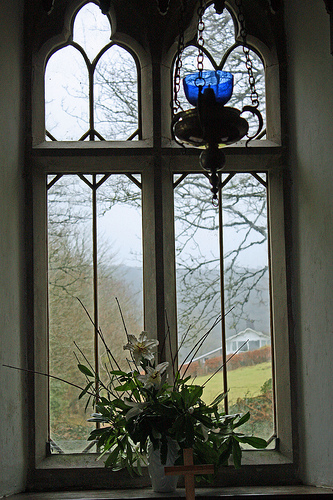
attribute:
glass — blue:
[182, 72, 233, 101]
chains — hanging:
[169, 2, 260, 119]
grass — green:
[183, 361, 273, 411]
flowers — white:
[124, 332, 160, 367]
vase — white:
[148, 437, 183, 491]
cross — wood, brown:
[164, 451, 212, 499]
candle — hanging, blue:
[169, 71, 252, 172]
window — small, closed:
[41, 7, 143, 141]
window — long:
[39, 5, 275, 450]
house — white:
[230, 326, 263, 354]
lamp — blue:
[183, 72, 234, 101]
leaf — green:
[220, 411, 248, 434]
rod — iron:
[212, 169, 218, 199]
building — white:
[233, 331, 265, 348]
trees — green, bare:
[52, 267, 135, 447]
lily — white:
[125, 333, 158, 366]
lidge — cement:
[15, 482, 329, 499]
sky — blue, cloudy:
[41, 2, 268, 271]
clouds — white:
[32, 6, 268, 268]